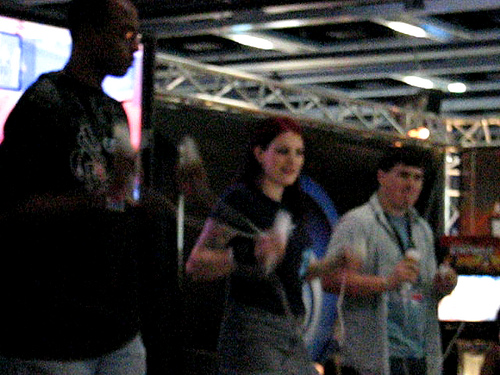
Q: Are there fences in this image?
A: No, there are no fences.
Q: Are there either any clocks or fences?
A: No, there are no fences or clocks.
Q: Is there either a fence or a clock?
A: No, there are no fences or clocks.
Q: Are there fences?
A: No, there are no fences.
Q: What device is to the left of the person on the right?
A: The device is a controller.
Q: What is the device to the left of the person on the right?
A: The device is a controller.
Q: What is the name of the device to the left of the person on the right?
A: The device is a controller.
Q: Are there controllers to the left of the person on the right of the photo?
A: Yes, there is a controller to the left of the person.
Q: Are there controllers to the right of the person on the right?
A: No, the controller is to the left of the person.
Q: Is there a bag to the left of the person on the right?
A: No, there is a controller to the left of the person.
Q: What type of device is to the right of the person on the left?
A: The device is a controller.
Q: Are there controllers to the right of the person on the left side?
A: Yes, there is a controller to the right of the person.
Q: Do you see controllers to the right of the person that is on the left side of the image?
A: Yes, there is a controller to the right of the person.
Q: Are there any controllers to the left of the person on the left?
A: No, the controller is to the right of the person.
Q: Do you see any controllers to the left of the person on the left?
A: No, the controller is to the right of the person.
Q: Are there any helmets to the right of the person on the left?
A: No, there is a controller to the right of the person.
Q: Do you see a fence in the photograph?
A: No, there are no fences.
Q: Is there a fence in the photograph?
A: No, there are no fences.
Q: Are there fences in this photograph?
A: No, there are no fences.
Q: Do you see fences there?
A: No, there are no fences.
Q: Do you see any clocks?
A: No, there are no clocks.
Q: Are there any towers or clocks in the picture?
A: No, there are no clocks or towers.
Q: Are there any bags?
A: No, there are no bags.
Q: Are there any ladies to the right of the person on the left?
A: Yes, there is a lady to the right of the person.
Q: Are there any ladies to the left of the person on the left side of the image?
A: No, the lady is to the right of the person.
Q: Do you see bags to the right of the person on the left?
A: No, there is a lady to the right of the person.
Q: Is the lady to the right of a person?
A: Yes, the lady is to the right of a person.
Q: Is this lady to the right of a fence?
A: No, the lady is to the right of a person.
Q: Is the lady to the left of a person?
A: No, the lady is to the right of a person.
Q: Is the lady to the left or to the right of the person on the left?
A: The lady is to the right of the person.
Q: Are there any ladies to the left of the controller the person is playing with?
A: Yes, there is a lady to the left of the controller.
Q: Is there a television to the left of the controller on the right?
A: No, there is a lady to the left of the controller.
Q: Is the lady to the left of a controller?
A: Yes, the lady is to the left of a controller.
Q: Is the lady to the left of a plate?
A: No, the lady is to the left of a controller.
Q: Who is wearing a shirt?
A: The lady is wearing a shirt.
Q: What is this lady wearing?
A: The lady is wearing a shirt.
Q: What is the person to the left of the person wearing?
A: The lady is wearing a shirt.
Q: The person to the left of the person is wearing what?
A: The lady is wearing a shirt.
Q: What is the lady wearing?
A: The lady is wearing a shirt.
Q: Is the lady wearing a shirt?
A: Yes, the lady is wearing a shirt.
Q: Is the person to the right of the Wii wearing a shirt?
A: Yes, the lady is wearing a shirt.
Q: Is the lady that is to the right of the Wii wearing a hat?
A: No, the lady is wearing a shirt.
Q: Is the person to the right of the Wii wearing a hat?
A: No, the lady is wearing a shirt.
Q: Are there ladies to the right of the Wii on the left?
A: Yes, there is a lady to the right of the Wii.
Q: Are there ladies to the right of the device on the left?
A: Yes, there is a lady to the right of the Wii.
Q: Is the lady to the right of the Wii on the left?
A: Yes, the lady is to the right of the Wii.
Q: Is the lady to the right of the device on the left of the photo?
A: Yes, the lady is to the right of the Wii.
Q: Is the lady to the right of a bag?
A: No, the lady is to the right of the Wii.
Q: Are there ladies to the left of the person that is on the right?
A: Yes, there is a lady to the left of the person.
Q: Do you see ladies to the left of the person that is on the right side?
A: Yes, there is a lady to the left of the person.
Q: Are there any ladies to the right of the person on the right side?
A: No, the lady is to the left of the person.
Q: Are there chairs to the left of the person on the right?
A: No, there is a lady to the left of the person.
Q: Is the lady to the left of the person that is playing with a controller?
A: Yes, the lady is to the left of the person.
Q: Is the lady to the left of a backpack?
A: No, the lady is to the left of the person.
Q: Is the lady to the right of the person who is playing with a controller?
A: No, the lady is to the left of the person.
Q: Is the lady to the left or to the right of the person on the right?
A: The lady is to the left of the person.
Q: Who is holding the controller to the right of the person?
A: The lady is holding the controller.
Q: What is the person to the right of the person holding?
A: The lady is holding the controller.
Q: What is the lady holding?
A: The lady is holding the controller.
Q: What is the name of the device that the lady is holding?
A: The device is a controller.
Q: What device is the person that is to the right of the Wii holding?
A: The lady is holding the controller.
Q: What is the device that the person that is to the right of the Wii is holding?
A: The device is a controller.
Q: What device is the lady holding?
A: The lady is holding the controller.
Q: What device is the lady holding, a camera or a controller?
A: The lady is holding a controller.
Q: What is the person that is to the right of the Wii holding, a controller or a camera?
A: The lady is holding a controller.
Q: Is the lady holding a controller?
A: Yes, the lady is holding a controller.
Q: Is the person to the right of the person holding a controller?
A: Yes, the lady is holding a controller.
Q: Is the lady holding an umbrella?
A: No, the lady is holding a controller.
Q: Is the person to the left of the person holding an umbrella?
A: No, the lady is holding a controller.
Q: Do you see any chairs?
A: No, there are no chairs.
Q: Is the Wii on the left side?
A: Yes, the Wii is on the left of the image.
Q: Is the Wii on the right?
A: No, the Wii is on the left of the image.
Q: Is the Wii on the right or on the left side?
A: The Wii is on the left of the image.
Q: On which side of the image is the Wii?
A: The Wii is on the left of the image.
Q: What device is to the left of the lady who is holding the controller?
A: The device is a Wii.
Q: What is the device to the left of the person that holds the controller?
A: The device is a Wii.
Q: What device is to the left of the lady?
A: The device is a Wii.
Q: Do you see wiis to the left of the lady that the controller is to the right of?
A: Yes, there is a Wii to the left of the lady.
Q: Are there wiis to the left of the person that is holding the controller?
A: Yes, there is a Wii to the left of the lady.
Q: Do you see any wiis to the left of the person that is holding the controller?
A: Yes, there is a Wii to the left of the lady.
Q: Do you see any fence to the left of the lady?
A: No, there is a Wii to the left of the lady.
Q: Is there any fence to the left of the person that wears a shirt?
A: No, there is a Wii to the left of the lady.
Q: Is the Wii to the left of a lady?
A: Yes, the Wii is to the left of a lady.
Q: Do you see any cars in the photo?
A: No, there are no cars.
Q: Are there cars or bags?
A: No, there are no cars or bags.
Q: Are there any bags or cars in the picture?
A: No, there are no cars or bags.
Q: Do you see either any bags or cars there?
A: No, there are no cars or bags.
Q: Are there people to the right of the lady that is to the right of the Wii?
A: Yes, there is a person to the right of the lady.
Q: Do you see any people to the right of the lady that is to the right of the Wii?
A: Yes, there is a person to the right of the lady.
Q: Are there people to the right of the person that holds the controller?
A: Yes, there is a person to the right of the lady.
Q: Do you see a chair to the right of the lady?
A: No, there is a person to the right of the lady.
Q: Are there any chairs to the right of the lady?
A: No, there is a person to the right of the lady.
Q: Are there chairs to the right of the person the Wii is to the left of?
A: No, there is a person to the right of the lady.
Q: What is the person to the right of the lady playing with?
A: The person is playing with a controller.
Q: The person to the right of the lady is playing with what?
A: The person is playing with a controller.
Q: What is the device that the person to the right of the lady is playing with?
A: The device is a controller.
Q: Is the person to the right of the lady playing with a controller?
A: Yes, the person is playing with a controller.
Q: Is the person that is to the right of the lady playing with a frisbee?
A: No, the person is playing with a controller.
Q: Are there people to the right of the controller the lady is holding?
A: Yes, there is a person to the right of the controller.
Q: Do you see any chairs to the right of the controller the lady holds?
A: No, there is a person to the right of the controller.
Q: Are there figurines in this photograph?
A: No, there are no figurines.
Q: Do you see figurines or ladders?
A: No, there are no figurines or ladders.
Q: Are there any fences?
A: No, there are no fences.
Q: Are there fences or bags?
A: No, there are no fences or bags.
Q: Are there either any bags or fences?
A: No, there are no fences or bags.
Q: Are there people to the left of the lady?
A: Yes, there is a person to the left of the lady.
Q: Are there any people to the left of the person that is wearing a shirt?
A: Yes, there is a person to the left of the lady.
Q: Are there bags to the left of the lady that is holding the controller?
A: No, there is a person to the left of the lady.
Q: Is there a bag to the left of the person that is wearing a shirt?
A: No, there is a person to the left of the lady.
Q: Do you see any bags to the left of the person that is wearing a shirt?
A: No, there is a person to the left of the lady.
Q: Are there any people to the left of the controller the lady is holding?
A: Yes, there is a person to the left of the controller.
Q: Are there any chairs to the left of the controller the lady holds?
A: No, there is a person to the left of the controller.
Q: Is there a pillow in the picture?
A: No, there are no pillows.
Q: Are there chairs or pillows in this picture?
A: No, there are no pillows or chairs.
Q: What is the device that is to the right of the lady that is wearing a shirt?
A: The device is a controller.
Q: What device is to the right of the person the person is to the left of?
A: The device is a controller.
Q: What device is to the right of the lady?
A: The device is a controller.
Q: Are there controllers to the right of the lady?
A: Yes, there is a controller to the right of the lady.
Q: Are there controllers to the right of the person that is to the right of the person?
A: Yes, there is a controller to the right of the lady.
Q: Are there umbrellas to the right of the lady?
A: No, there is a controller to the right of the lady.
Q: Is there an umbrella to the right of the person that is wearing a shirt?
A: No, there is a controller to the right of the lady.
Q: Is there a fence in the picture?
A: No, there are no fences.